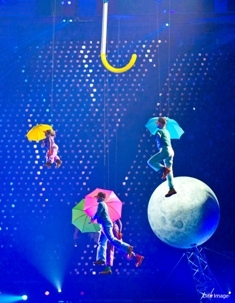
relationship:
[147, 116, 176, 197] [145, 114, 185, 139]
man on umbrella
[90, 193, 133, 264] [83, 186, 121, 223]
person on umbrella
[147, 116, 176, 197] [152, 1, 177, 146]
man hanging from wires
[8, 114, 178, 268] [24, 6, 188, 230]
people holding umbrellas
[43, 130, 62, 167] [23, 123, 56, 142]
girl holding umbrella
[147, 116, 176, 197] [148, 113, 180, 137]
man holding umbrella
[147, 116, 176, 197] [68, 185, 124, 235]
man holding umbrellas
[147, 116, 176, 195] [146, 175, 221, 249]
man standing on moon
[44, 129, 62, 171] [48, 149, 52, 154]
people holding book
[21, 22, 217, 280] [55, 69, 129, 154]
stripe and panel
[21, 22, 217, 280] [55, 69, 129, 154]
stripe of panel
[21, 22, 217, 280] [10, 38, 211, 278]
stripe of dots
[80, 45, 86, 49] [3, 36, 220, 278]
dots against panel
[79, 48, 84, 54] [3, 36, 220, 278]
dots against panel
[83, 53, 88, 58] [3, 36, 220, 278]
dots against panel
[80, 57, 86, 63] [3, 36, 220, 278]
dots against panel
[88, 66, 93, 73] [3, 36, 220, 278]
dots against panel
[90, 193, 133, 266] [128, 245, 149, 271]
person wearing boot